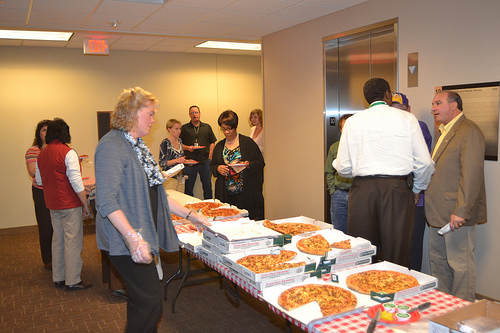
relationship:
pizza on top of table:
[279, 282, 357, 315] [164, 189, 477, 331]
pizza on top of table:
[348, 268, 418, 297] [164, 189, 477, 331]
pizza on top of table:
[237, 248, 304, 272] [164, 189, 477, 331]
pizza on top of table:
[296, 235, 352, 258] [164, 189, 477, 331]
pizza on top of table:
[264, 217, 321, 237] [164, 189, 477, 331]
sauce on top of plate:
[383, 300, 412, 320] [367, 301, 421, 326]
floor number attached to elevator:
[329, 116, 337, 127] [323, 17, 403, 221]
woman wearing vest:
[34, 119, 100, 290] [35, 140, 82, 209]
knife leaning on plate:
[366, 309, 383, 332] [367, 301, 421, 326]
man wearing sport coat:
[420, 91, 487, 302] [421, 114, 487, 228]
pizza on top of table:
[202, 206, 239, 219] [164, 189, 477, 331]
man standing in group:
[420, 91, 487, 302] [323, 78, 491, 299]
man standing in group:
[332, 78, 435, 268] [323, 78, 491, 299]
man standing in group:
[392, 91, 432, 154] [323, 78, 491, 299]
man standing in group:
[323, 114, 352, 235] [323, 78, 491, 299]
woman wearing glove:
[93, 87, 181, 332] [124, 227, 155, 265]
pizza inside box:
[237, 248, 304, 272] [220, 245, 316, 283]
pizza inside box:
[348, 268, 418, 297] [331, 259, 439, 305]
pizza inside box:
[296, 235, 352, 258] [285, 226, 370, 262]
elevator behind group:
[323, 17, 403, 221] [323, 78, 491, 299]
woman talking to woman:
[34, 119, 100, 290] [25, 120, 63, 271]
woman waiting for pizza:
[210, 109, 267, 219] [202, 206, 239, 219]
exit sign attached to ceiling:
[82, 37, 110, 57] [0, 1, 369, 58]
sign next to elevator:
[406, 51, 419, 88] [323, 17, 403, 221]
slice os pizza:
[330, 238, 351, 252] [296, 235, 352, 258]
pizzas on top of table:
[182, 198, 440, 330] [164, 189, 477, 331]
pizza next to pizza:
[279, 282, 357, 315] [348, 268, 418, 297]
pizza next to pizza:
[237, 248, 304, 272] [279, 282, 357, 315]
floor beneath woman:
[1, 223, 302, 331] [93, 87, 181, 332]